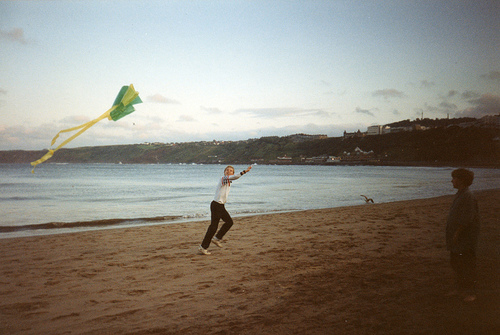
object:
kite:
[28, 84, 141, 173]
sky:
[2, 1, 499, 150]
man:
[198, 162, 264, 256]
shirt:
[211, 168, 248, 206]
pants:
[200, 200, 234, 249]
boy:
[445, 168, 482, 303]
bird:
[360, 194, 375, 204]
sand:
[0, 187, 498, 334]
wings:
[360, 195, 378, 202]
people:
[200, 161, 482, 305]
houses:
[143, 114, 497, 167]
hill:
[0, 113, 498, 165]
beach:
[0, 188, 499, 333]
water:
[1, 162, 499, 238]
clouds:
[0, 22, 499, 150]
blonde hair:
[224, 165, 235, 173]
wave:
[1, 207, 308, 233]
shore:
[2, 185, 500, 243]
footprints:
[7, 189, 500, 329]